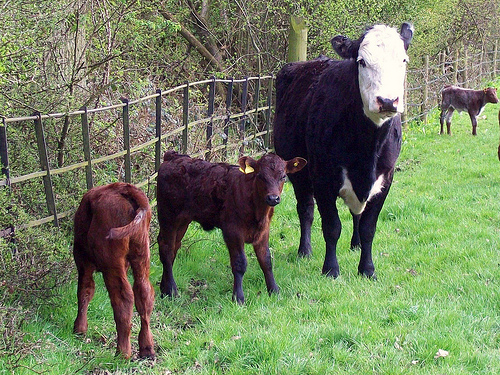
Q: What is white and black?
A: Cow.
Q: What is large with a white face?
A: Cow.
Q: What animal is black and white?
A: Large cow.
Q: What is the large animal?
A: Adult cow.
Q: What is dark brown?
A: Calf.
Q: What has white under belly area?
A: Large cow.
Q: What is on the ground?
A: Grass.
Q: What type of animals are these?
A: Cows.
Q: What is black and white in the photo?
A: Cow.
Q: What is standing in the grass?
A: Baby cow.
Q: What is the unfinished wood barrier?
A: Fence.